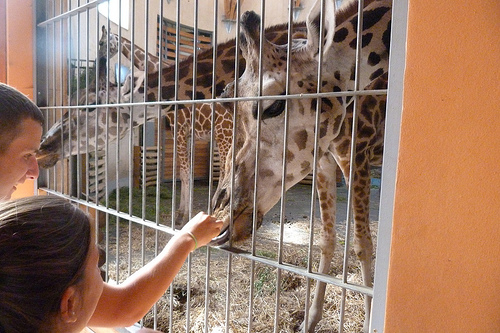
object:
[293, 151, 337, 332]
leg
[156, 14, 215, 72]
gate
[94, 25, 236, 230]
giraffes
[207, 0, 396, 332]
giraffe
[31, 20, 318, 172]
giraffe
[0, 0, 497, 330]
enclosure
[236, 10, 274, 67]
horns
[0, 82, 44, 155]
hair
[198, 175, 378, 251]
concrete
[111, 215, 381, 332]
hay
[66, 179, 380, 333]
grass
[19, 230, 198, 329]
arm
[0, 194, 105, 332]
female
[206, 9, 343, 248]
head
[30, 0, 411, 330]
cage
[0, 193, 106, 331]
lady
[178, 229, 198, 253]
band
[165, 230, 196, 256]
wrist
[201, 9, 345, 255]
carpet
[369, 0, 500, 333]
wall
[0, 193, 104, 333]
child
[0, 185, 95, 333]
girl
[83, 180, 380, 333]
ground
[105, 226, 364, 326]
floor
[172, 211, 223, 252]
hand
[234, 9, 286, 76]
antler